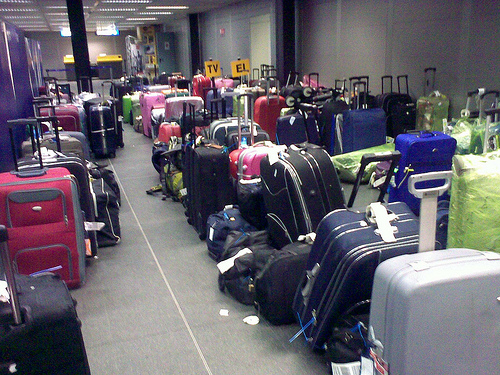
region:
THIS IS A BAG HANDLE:
[0, 228, 25, 327]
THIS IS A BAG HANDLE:
[390, 67, 410, 97]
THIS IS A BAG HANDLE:
[380, 70, 392, 93]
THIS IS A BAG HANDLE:
[5, 114, 42, 176]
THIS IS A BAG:
[0, 265, 78, 373]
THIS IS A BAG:
[10, 165, 90, 279]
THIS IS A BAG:
[68, 156, 95, 242]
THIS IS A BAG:
[40, 105, 79, 126]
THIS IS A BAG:
[143, 89, 163, 131]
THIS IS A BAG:
[177, 143, 233, 208]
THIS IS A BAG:
[268, 145, 336, 220]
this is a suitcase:
[368, 167, 499, 374]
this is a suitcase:
[4, 110, 89, 294]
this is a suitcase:
[260, 140, 350, 251]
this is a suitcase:
[167, 90, 242, 226]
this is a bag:
[317, 302, 375, 369]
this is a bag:
[205, 205, 255, 260]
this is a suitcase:
[87, 91, 126, 156]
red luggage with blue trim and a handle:
[8, 153, 91, 291]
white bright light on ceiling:
[93, 24, 120, 40]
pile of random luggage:
[105, 59, 474, 345]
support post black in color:
[59, 8, 102, 93]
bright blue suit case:
[397, 130, 457, 174]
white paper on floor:
[239, 310, 263, 328]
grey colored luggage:
[370, 244, 493, 370]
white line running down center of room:
[126, 219, 209, 347]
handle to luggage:
[407, 167, 460, 244]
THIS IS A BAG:
[13, 274, 73, 359]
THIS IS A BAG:
[3, 169, 82, 263]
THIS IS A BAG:
[90, 105, 114, 151]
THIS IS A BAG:
[214, 212, 244, 237]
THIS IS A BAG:
[308, 215, 377, 297]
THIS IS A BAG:
[396, 260, 483, 352]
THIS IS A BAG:
[398, 134, 455, 176]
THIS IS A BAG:
[348, 105, 381, 148]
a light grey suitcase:
[368, 248, 498, 374]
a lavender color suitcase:
[137, 90, 169, 135]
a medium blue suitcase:
[390, 128, 461, 222]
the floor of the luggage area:
[64, 109, 332, 374]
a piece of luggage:
[0, 121, 109, 292]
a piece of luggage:
[253, 123, 346, 239]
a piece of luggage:
[295, 195, 425, 352]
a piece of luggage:
[384, 163, 497, 372]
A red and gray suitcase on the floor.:
[16, 170, 81, 283]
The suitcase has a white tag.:
[371, 196, 389, 240]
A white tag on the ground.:
[241, 308, 271, 328]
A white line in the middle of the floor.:
[141, 225, 196, 350]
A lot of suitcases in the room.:
[166, 80, 423, 260]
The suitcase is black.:
[268, 142, 329, 222]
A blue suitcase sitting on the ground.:
[203, 203, 250, 255]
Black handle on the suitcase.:
[9, 114, 39, 164]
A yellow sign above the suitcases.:
[222, 56, 260, 83]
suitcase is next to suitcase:
[368, 169, 499, 374]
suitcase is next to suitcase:
[294, 198, 419, 353]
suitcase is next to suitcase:
[264, 145, 340, 245]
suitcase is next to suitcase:
[186, 145, 228, 235]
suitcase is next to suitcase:
[329, 105, 385, 161]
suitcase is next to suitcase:
[389, 133, 454, 210]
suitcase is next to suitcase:
[1, 271, 99, 374]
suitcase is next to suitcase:
[0, 168, 86, 286]